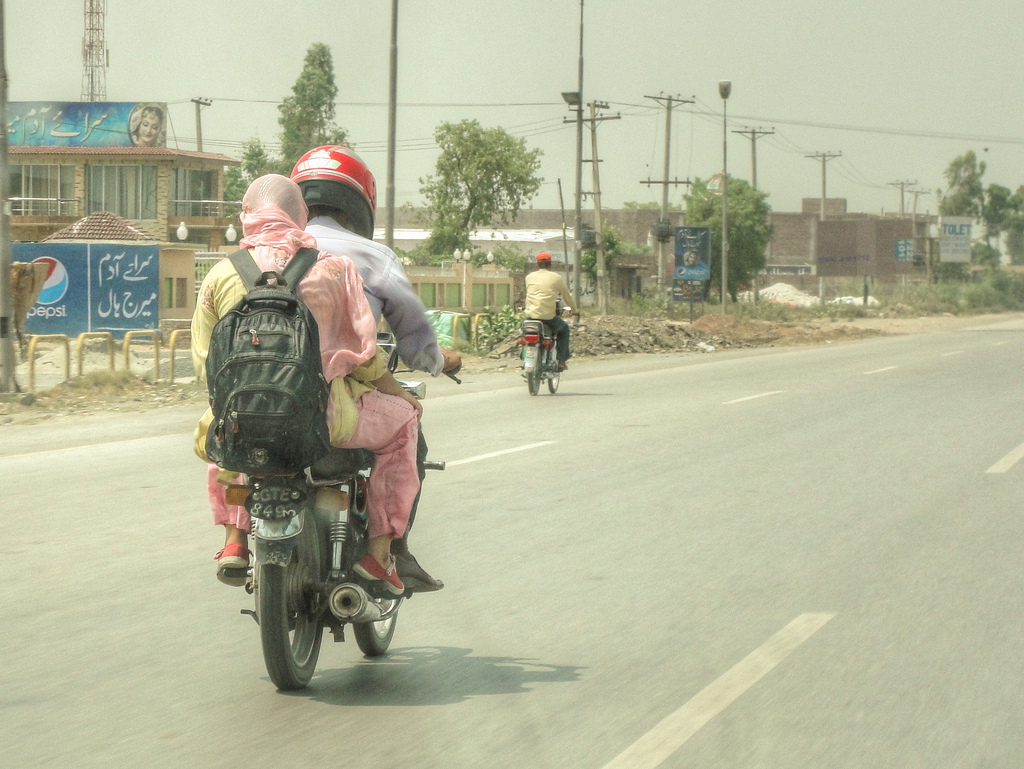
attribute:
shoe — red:
[358, 558, 406, 593]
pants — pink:
[311, 372, 423, 537]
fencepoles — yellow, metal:
[29, 329, 191, 387]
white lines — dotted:
[574, 592, 862, 760]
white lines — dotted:
[988, 417, 1023, 488]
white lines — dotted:
[443, 428, 564, 476]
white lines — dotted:
[717, 373, 793, 419]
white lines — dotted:
[844, 354, 906, 387]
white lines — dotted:
[935, 343, 974, 367]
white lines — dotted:
[992, 333, 1016, 350]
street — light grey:
[563, 417, 953, 684]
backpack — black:
[204, 271, 335, 472]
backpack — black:
[200, 228, 350, 484]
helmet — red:
[290, 150, 378, 233]